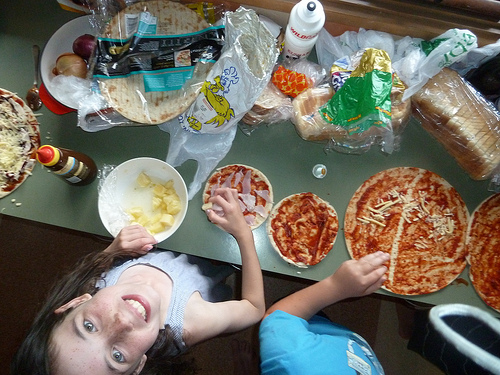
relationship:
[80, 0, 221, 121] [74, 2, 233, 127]
pita bread in plastic wrapping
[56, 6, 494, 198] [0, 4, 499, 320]
bags on counter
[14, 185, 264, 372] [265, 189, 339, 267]
girl decorating cheese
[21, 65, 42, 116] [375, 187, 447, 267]
spoon spreagin sauce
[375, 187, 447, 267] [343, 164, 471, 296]
sauce around pizza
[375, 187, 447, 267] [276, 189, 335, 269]
sauce around tortillas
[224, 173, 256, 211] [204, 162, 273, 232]
toppings on pizza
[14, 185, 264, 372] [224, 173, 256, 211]
girl putting toppings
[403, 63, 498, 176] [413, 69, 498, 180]
loaves of bread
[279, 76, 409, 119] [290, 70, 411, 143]
loaves of loaves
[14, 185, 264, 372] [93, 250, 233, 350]
girl wearing a top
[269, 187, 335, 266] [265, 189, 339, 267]
tomato sauce on cheese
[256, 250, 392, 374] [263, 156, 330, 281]
child putting on cheese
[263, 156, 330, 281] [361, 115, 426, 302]
cheese on pizza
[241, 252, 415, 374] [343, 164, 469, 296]
child making pizza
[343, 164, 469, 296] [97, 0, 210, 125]
pizza made with a tortilla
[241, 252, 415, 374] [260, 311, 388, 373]
child wearing a top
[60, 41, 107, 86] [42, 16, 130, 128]
onions in a bowl